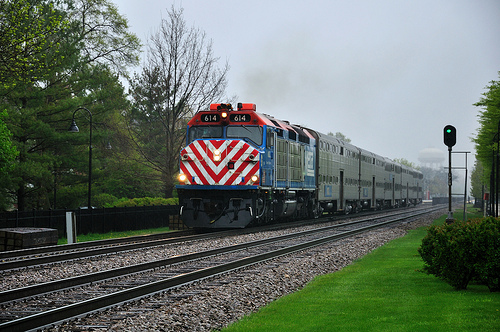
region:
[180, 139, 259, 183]
Red and white chevron pattern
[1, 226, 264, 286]
two train tracks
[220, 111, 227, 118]
Light at the front of the train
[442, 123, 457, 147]
Green traffic light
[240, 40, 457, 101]
Smoke in the sky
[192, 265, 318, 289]
Rocks alongside the train tracks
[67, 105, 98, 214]
Street light alongside the train tracks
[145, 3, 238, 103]
A leafless tree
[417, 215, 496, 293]
A green bush in the grass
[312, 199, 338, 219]
Train wheels on the train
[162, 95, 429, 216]
train on the track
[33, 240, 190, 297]
track train is on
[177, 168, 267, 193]
lights on the train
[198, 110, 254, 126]
numbers on the train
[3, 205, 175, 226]
fence near the tracks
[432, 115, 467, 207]
light on a pole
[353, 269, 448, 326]
green space near track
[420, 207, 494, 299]
shrub on green space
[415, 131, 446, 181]
water tower behind train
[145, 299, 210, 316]
rocks near the tracks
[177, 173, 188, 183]
the bright headlight of the train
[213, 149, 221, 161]
the bright headlight of the train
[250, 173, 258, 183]
the bright headlight of the train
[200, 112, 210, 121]
the number 6 on the train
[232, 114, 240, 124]
the number 6 on the train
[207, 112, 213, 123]
the number 1 on the train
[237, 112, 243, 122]
the number 1 on the train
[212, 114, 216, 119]
the number 4 on the train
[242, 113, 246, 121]
the number 4 on the train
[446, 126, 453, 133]
the green traffic light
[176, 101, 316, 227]
a red white and blue engine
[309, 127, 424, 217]
four gray train cars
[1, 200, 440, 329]
two train tracks with gravel all around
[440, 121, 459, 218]
a green light on a post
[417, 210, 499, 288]
a small green shrub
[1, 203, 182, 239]
a black colored fence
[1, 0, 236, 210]
tall trees on the left side of the train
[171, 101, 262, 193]
the train has three illuminated lights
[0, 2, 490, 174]
a light blue sky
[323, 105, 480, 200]
fog in the air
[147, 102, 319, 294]
the train is red and white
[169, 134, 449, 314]
the train is striped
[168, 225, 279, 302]
rocks are by the tracks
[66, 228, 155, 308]
the tracks are made of metal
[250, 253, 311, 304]
rocks are by the grass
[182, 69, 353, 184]
the train numbers are 614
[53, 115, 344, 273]
trees are by the train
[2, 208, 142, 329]
a rock is by the track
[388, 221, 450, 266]
a bush is by the grass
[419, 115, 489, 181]
a pole is behind the bush